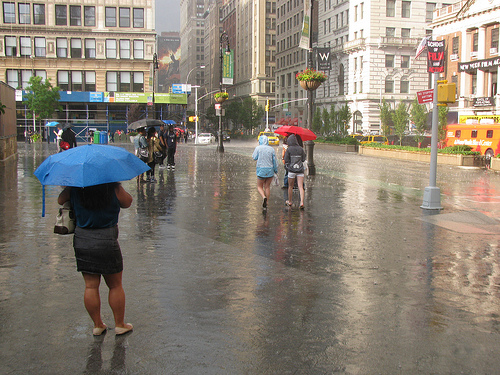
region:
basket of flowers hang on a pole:
[288, 72, 325, 99]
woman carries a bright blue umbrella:
[27, 143, 145, 343]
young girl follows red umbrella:
[273, 117, 315, 202]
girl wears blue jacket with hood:
[249, 122, 281, 211]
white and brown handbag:
[52, 199, 77, 239]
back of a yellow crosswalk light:
[433, 77, 463, 109]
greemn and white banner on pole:
[217, 44, 239, 93]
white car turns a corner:
[190, 122, 223, 151]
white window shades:
[1, 30, 151, 95]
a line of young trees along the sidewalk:
[315, 97, 437, 146]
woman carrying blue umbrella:
[29, 137, 161, 341]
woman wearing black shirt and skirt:
[29, 135, 163, 351]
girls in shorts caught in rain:
[247, 110, 340, 216]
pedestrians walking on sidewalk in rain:
[244, 112, 336, 222]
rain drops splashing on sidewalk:
[316, 239, 445, 342]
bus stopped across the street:
[422, 110, 497, 165]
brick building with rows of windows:
[7, 7, 163, 99]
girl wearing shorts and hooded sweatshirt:
[242, 131, 289, 226]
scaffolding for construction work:
[17, 74, 201, 151]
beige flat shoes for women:
[70, 298, 150, 343]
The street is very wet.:
[4, 139, 498, 371]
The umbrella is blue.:
[33, 142, 151, 190]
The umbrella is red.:
[273, 123, 317, 145]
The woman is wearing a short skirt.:
[71, 225, 126, 280]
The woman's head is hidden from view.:
[57, 183, 134, 337]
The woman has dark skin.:
[58, 184, 135, 337]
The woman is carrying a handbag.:
[53, 200, 74, 236]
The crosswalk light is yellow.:
[433, 80, 460, 107]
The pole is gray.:
[421, 70, 445, 212]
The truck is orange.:
[439, 123, 499, 157]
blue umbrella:
[27, 140, 158, 202]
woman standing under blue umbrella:
[38, 145, 148, 353]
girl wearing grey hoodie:
[276, 130, 318, 216]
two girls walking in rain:
[246, 126, 313, 215]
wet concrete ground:
[170, 200, 445, 338]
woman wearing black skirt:
[57, 166, 138, 349]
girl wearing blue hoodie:
[252, 130, 279, 202]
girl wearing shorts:
[279, 135, 311, 214]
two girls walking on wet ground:
[240, 125, 317, 215]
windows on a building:
[1, 24, 152, 63]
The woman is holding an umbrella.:
[31, 140, 153, 347]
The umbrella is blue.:
[25, 140, 150, 235]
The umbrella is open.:
[30, 136, 151, 221]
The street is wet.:
[0, 131, 499, 371]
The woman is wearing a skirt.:
[30, 136, 150, 336]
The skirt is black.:
[25, 136, 150, 337]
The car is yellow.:
[255, 125, 280, 145]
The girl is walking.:
[242, 112, 277, 217]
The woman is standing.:
[30, 130, 155, 351]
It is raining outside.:
[18, 0, 460, 374]